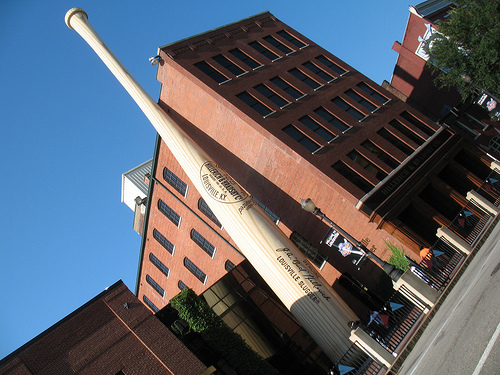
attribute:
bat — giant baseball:
[55, 7, 312, 361]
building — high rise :
[182, 10, 486, 234]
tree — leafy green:
[417, 7, 499, 122]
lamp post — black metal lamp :
[290, 192, 407, 281]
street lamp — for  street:
[295, 198, 434, 309]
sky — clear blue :
[6, 26, 128, 272]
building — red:
[30, 145, 302, 307]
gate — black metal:
[422, 244, 466, 271]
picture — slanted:
[3, 4, 498, 374]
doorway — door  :
[393, 202, 458, 259]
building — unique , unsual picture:
[118, 5, 498, 370]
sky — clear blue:
[2, 2, 428, 364]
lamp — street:
[299, 192, 321, 217]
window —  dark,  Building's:
[273, 71, 309, 101]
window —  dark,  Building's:
[363, 138, 403, 170]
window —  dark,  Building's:
[402, 111, 439, 136]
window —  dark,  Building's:
[189, 61, 229, 86]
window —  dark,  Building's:
[155, 200, 184, 231]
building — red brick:
[125, 27, 461, 275]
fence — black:
[321, 157, 496, 374]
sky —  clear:
[8, 65, 100, 270]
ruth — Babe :
[65, 14, 384, 365]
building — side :
[1, 272, 243, 369]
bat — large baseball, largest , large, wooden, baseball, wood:
[58, 6, 363, 368]